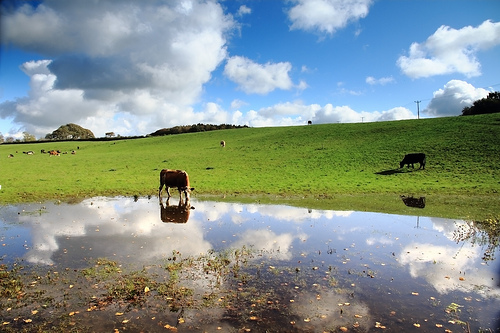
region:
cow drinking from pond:
[147, 161, 199, 199]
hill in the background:
[41, 117, 98, 142]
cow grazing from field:
[389, 150, 426, 172]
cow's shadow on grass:
[370, 163, 422, 178]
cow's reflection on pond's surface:
[155, 196, 197, 228]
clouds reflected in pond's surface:
[32, 200, 495, 332]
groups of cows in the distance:
[12, 138, 80, 162]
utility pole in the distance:
[407, 92, 424, 121]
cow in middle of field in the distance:
[216, 140, 231, 148]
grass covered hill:
[10, 128, 478, 200]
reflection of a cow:
[159, 199, 224, 235]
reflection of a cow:
[149, 187, 203, 239]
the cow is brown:
[142, 162, 223, 207]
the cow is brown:
[158, 156, 235, 225]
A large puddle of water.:
[2, 201, 494, 331]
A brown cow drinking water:
[156, 166, 193, 201]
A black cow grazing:
[398, 152, 433, 170]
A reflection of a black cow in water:
[401, 193, 427, 215]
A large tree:
[45, 118, 103, 141]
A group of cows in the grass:
[8, 148, 86, 158]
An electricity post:
[410, 99, 428, 118]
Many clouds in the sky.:
[2, 1, 499, 141]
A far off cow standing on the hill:
[307, 119, 314, 126]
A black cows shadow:
[372, 165, 419, 176]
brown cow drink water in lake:
[147, 165, 206, 203]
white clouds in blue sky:
[2, 5, 57, 44]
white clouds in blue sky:
[10, 44, 83, 84]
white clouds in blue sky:
[10, 83, 92, 124]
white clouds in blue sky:
[81, 11, 154, 55]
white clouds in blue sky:
[129, 53, 200, 101]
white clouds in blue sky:
[188, 18, 257, 59]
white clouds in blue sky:
[183, 48, 306, 90]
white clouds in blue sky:
[242, 2, 359, 50]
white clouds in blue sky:
[332, 34, 498, 72]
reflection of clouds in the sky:
[214, 212, 303, 257]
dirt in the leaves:
[61, 285, 166, 325]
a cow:
[397, 145, 432, 170]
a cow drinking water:
[158, 165, 202, 206]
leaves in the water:
[310, 266, 384, 324]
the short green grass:
[235, 126, 336, 182]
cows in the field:
[15, 142, 90, 163]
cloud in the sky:
[430, 85, 475, 115]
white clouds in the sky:
[291, 100, 371, 121]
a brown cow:
[156, 163, 208, 210]